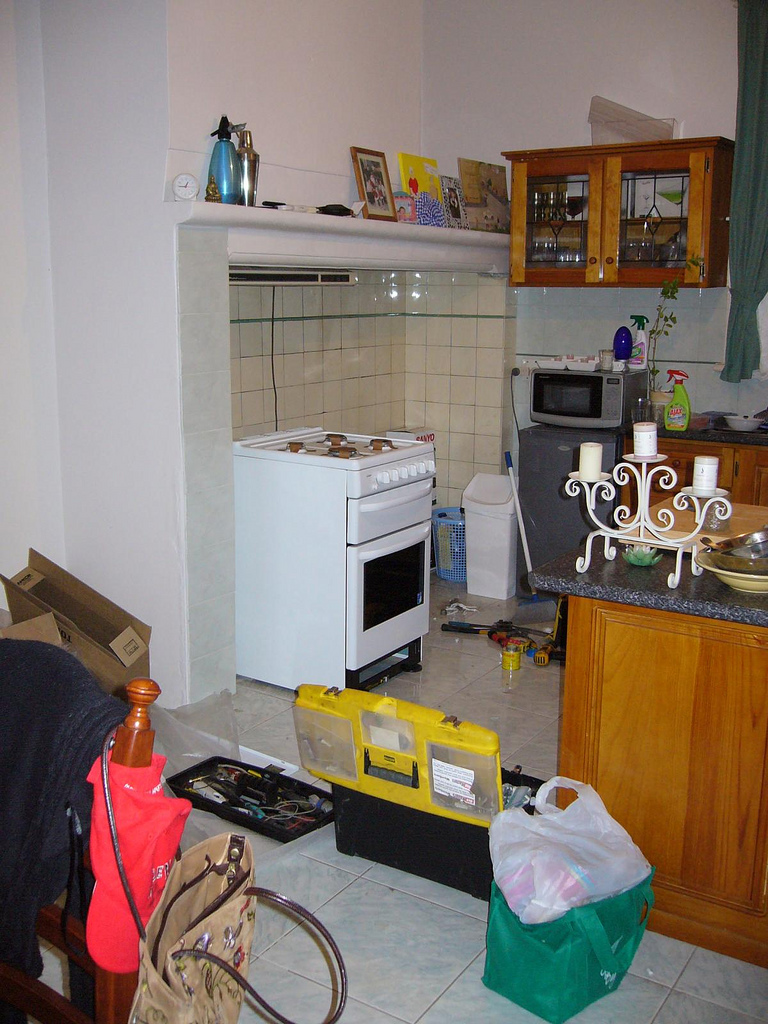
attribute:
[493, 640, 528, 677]
jar — yellow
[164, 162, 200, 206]
clock — white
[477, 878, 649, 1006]
bag — green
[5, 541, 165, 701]
emptybox — empty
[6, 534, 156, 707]
box — cardboard